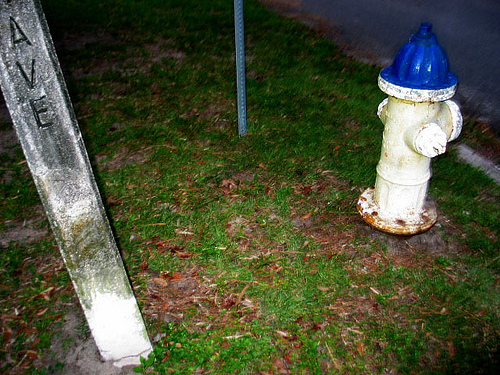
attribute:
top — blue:
[374, 22, 463, 87]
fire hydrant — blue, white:
[352, 19, 461, 236]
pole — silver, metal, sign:
[230, 12, 251, 134]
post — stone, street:
[13, 21, 153, 359]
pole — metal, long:
[224, 0, 253, 141]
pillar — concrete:
[6, 4, 156, 373]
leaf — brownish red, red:
[170, 267, 199, 290]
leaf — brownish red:
[239, 291, 257, 312]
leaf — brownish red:
[339, 302, 355, 318]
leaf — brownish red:
[348, 336, 369, 356]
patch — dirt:
[48, 309, 84, 361]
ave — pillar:
[1, 11, 61, 132]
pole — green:
[228, 4, 253, 144]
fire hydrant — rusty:
[342, 16, 469, 243]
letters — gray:
[6, 13, 60, 149]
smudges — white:
[75, 273, 155, 365]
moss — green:
[59, 213, 126, 283]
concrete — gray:
[344, 11, 485, 49]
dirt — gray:
[64, 338, 114, 372]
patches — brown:
[155, 271, 260, 325]